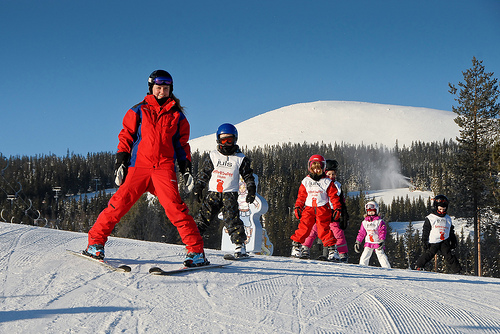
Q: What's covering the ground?
A: Snow.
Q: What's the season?
A: Winter.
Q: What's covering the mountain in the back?
A: Snow.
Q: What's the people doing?
A: Skiing.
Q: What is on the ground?
A: Snow.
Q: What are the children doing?
A: Skiing.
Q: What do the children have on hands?
A: Gloves.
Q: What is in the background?
A: Trees.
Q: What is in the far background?
A: Mountain.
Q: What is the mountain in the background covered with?
A: Snow.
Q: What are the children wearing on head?
A: Helmets.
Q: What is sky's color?
A: Blue.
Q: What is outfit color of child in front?
A: Red and Blue.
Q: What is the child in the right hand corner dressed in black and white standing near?
A: Pine Tree.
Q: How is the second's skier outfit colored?
A: Black and white.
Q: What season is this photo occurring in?
A: Winter.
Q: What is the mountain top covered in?
A: Snow.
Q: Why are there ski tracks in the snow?
A: People were skiing in it.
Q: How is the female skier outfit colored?
A: Red.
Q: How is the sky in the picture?
A: Clear.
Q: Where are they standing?
A: On snow.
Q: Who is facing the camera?
A: Children.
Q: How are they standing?
A: Wide-legged.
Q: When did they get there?
A: Afternoon.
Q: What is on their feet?
A: Skis.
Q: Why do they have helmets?
A: Safety.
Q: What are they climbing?
A: A hill.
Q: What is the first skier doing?
A: Smiling.